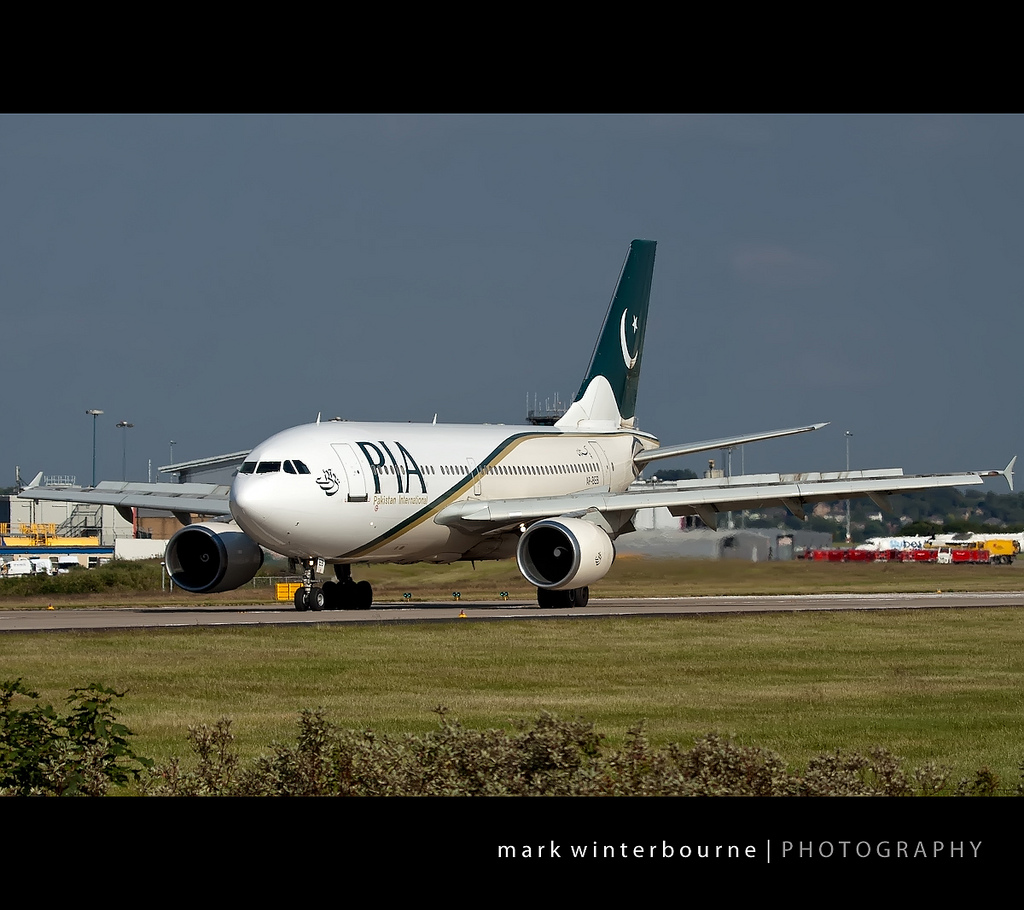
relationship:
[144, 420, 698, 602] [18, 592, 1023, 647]
airplane on runway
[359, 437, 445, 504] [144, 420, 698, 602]
pia on airplane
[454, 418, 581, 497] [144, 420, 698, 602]
stripes on airplane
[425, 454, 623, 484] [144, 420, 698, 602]
windows on airplane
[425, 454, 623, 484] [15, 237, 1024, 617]
windows on airplane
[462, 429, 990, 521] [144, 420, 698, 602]
wings on airplane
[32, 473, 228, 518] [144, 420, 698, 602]
wing on airplane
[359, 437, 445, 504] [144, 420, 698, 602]
pia on side of airplane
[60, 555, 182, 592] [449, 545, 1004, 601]
shrubs on field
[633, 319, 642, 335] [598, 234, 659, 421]
star on tail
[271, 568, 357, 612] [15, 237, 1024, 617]
landing gear under airplane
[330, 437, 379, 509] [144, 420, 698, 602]
door on airplane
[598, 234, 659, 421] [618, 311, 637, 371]
tail has moon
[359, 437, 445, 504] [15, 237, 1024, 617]
pia on side of airplane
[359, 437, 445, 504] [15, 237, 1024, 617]
pia on airplane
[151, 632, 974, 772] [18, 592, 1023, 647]
grass near runway